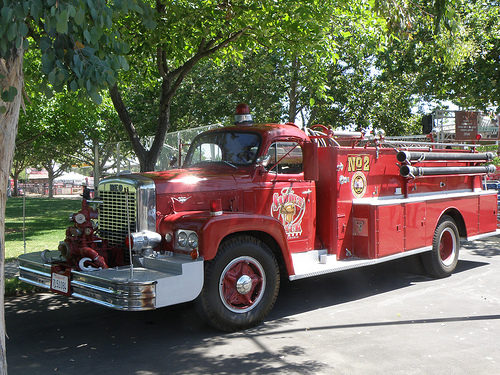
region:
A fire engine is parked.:
[5, 5, 497, 370]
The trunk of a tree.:
[0, 55, 25, 371]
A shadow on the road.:
[305, 310, 497, 345]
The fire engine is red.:
[15, 95, 498, 340]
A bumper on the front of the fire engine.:
[15, 241, 205, 308]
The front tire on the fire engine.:
[196, 237, 278, 329]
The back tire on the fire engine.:
[417, 215, 462, 275]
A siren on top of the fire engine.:
[230, 95, 251, 125]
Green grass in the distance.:
[28, 195, 56, 235]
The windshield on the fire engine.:
[182, 126, 266, 166]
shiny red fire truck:
[15, 43, 495, 338]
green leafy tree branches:
[129, 66, 166, 136]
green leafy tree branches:
[214, 58, 286, 113]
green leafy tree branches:
[279, 47, 345, 123]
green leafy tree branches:
[310, 55, 358, 124]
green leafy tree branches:
[364, 53, 416, 121]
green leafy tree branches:
[436, 9, 498, 123]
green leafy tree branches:
[244, 3, 333, 58]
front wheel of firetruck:
[191, 224, 296, 342]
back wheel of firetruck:
[423, 211, 470, 291]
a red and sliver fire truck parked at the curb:
[10, 97, 498, 334]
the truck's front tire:
[203, 232, 282, 329]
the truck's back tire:
[429, 212, 461, 278]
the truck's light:
[234, 97, 252, 124]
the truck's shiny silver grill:
[92, 176, 154, 258]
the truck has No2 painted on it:
[345, 150, 370, 173]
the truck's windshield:
[184, 129, 259, 171]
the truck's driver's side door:
[262, 135, 314, 239]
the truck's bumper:
[17, 239, 200, 309]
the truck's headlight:
[172, 229, 197, 253]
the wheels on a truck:
[173, 227, 328, 334]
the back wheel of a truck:
[407, 215, 467, 281]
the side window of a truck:
[240, 113, 325, 188]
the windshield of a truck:
[171, 115, 269, 177]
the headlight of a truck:
[134, 226, 205, 264]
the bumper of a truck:
[26, 190, 198, 327]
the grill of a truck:
[44, 178, 164, 274]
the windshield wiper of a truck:
[191, 129, 311, 173]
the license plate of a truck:
[28, 258, 83, 325]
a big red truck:
[99, 79, 414, 339]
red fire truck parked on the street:
[16, 99, 498, 331]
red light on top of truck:
[232, 100, 253, 123]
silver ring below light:
[233, 113, 254, 123]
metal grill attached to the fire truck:
[97, 177, 154, 239]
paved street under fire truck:
[8, 234, 499, 373]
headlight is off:
[176, 232, 197, 247]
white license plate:
[48, 273, 69, 293]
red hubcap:
[223, 261, 261, 307]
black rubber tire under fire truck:
[196, 232, 281, 322]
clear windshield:
[183, 130, 257, 166]